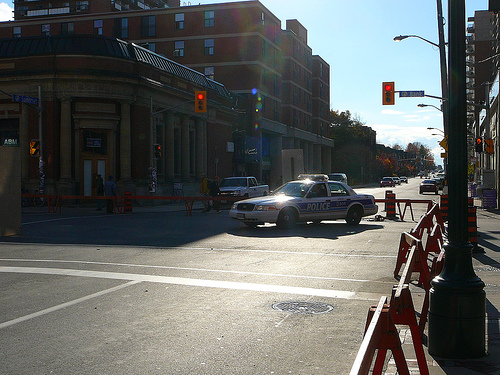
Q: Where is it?
A: This is at the road.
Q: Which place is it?
A: It is a road.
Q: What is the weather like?
A: It is clear.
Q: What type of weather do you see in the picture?
A: It is clear.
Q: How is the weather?
A: It is clear.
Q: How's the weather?
A: It is clear.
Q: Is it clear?
A: Yes, it is clear.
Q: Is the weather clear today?
A: Yes, it is clear.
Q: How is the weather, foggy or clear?
A: It is clear.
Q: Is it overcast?
A: No, it is clear.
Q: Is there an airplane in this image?
A: No, there are no airplanes.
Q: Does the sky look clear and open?
A: Yes, the sky is clear and open.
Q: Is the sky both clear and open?
A: Yes, the sky is clear and open.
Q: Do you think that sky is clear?
A: Yes, the sky is clear.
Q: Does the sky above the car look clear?
A: Yes, the sky is clear.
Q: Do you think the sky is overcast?
A: No, the sky is clear.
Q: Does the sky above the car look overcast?
A: No, the sky is clear.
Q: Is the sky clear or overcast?
A: The sky is clear.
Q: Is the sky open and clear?
A: Yes, the sky is open and clear.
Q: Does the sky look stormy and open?
A: No, the sky is open but clear.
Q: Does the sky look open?
A: Yes, the sky is open.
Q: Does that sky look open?
A: Yes, the sky is open.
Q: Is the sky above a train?
A: No, the sky is above a car.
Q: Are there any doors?
A: Yes, there are doors.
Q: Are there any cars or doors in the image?
A: Yes, there are doors.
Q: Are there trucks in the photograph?
A: Yes, there is a truck.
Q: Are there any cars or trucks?
A: Yes, there is a truck.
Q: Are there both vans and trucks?
A: No, there is a truck but no vans.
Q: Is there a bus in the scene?
A: No, there are no buses.